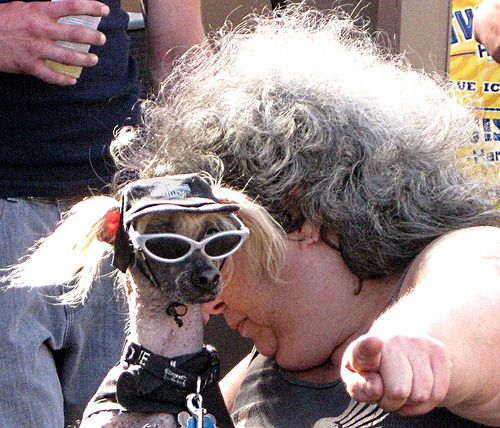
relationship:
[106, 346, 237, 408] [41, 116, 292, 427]
collar on dog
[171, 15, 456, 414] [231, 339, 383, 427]
woman has shirt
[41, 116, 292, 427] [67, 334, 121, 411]
dog with cape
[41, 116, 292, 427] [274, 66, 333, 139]
dog has hair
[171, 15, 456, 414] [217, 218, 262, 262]
woman with eye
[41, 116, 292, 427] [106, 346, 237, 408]
dog has collar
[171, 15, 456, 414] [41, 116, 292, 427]
woman and dog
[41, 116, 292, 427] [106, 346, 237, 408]
dog ha collar